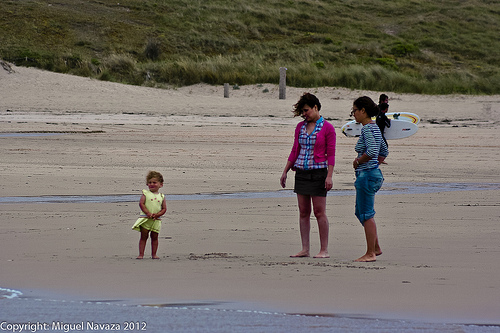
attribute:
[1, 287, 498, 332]
ocean — calm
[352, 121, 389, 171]
shirt — striped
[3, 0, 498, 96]
field — green, grassy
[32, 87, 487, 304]
beach — wet, sandy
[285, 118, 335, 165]
shirt — pink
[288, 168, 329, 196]
skirt — mini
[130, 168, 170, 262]
girl — small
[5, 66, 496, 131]
dirt — large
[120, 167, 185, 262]
girl — young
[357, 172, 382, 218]
jeans — denim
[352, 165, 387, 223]
capris — Rolled up, denim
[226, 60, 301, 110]
posts — wooden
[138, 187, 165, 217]
shirt — green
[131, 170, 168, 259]
girl — little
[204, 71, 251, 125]
pillar — small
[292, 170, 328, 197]
skirt — black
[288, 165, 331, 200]
shorts — black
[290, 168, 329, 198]
skirt — Short, black